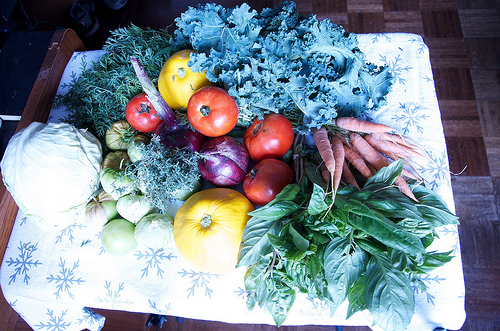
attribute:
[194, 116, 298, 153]
tomato — red and ripe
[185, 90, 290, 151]
tomatoes — red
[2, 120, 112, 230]
cabbage — green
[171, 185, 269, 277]
squash — yellow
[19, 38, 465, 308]
mat — white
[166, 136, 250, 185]
onions — red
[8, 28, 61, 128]
object — wooden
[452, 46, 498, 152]
floor — brown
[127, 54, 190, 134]
vegetable — green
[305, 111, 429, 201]
bunch — carrots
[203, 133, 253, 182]
vegetable — purple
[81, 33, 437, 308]
vegetables — small, green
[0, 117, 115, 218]
cabbage — green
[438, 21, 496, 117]
squares — brown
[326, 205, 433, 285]
leaves — green, medium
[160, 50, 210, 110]
vegetable — large, orange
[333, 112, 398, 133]
carrot — orange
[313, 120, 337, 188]
carrot — orange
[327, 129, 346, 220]
carrot — orange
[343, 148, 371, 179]
carrot — orange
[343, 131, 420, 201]
carrot — orange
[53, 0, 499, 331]
floor — brown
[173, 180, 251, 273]
squash — small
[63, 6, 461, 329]
greens — bright, leafy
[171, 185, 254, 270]
vegetable — large, orange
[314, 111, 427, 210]
carrots — orange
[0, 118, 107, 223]
cabbage — green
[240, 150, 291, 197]
tomato — red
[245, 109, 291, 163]
tomato — red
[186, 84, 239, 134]
tomato — red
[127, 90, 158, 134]
tomato — red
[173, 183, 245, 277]
squash — yellow 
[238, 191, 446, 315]
spinach — green 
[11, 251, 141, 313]
cloth — white 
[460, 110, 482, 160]
floor — tile wooden